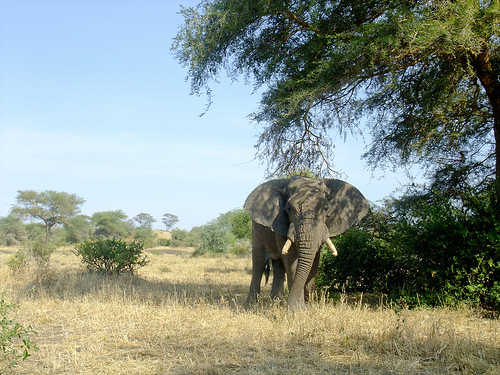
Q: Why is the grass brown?
A: Dry.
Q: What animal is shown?
A: Elephant.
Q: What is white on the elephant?
A: Tusk.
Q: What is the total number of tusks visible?
A: Two.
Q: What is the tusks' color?
A: White.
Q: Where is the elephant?
A: In the grass.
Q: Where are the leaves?
A: On the tree.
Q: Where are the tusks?
A: On the elephant.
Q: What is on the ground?
A: Grasses.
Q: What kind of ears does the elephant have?
A: Wide ears.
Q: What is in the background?
A: Green bush.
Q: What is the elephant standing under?
A: Tall tree.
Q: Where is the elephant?
A: In field.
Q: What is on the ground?
A: Brown grasses.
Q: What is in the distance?
A: Blue sky.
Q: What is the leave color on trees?
A: Green leaves.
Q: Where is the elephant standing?
A: Middle of field.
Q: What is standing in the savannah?
A: An elephant.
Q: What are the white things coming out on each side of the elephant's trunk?
A: Tusks.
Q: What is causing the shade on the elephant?
A: The tree.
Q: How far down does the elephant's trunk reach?
A: To the ground.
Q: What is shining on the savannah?
A: The sun.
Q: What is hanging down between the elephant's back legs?
A: It's tail.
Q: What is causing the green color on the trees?
A: The leaves.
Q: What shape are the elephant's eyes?
A: Round.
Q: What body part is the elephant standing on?
A: His legs.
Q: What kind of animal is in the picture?
A: Elephant.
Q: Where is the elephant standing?
A: In the shade.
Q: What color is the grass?
A: Brown.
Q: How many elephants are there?
A: One.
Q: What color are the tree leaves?
A: Green.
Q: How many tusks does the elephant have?
A: Two.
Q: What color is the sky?
A: Blue.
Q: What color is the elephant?
A: Grey.